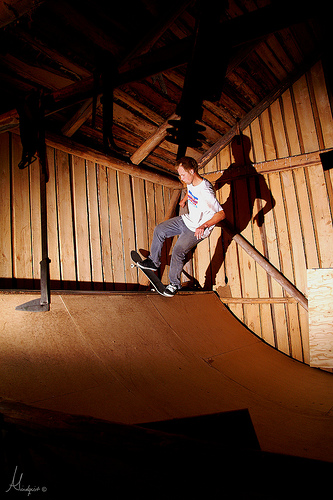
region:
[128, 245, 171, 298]
the skateboard the man is riding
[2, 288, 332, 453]
the ramp the man is skating on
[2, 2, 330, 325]
the building the man is skating in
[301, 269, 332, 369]
a board on the wall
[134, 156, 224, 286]
the man riding a skateboard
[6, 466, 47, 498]
the name in the corner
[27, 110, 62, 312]
the pole by the wall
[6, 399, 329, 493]
the wall by the ramp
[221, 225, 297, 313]
some poles on the wall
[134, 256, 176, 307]
the shoes on the man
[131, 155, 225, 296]
man on a skateboard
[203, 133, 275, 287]
shadow of man on the skateboard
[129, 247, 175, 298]
black skateboard man is on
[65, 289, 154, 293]
top ledge of skateboard ramp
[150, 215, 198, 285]
pants of man on skateboard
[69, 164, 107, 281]
wall behind skateboard ramp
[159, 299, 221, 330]
part of ramp below the skateboard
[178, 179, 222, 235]
shirt man on skateboard is wearing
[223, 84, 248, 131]
ceiling above the skateboarder's shadow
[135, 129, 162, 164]
part of wooden beam on ceiling over skateboarder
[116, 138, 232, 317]
a young man riding a skate board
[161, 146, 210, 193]
a young man with short hair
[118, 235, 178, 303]
a black skate board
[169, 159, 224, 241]
a young man wearing a white shirt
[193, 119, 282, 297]
a persons shadow on a wall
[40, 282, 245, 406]
a wooden skateboard ramp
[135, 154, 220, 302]
a young man wearing black tennis shoes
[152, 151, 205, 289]
a young man wearing grey pants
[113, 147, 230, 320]
a young man on a skateboard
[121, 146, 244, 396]
a young man on a skateboard ramp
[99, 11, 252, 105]
a brown wooden ceiling.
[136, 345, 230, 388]
a smooth skateboard ramp.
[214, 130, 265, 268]
a shadow of a man.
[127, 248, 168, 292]
a black skateboard.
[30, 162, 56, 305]
a black metal instrument.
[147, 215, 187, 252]
a man is wearing grey pants.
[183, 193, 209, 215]
a man is wearing a white red and blue shirt.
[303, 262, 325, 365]
a piece of board.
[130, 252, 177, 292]
a man is wearing black sneakers.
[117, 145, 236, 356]
a man is skateboarding down the ramp.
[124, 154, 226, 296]
The skateboarder currently riding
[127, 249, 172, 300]
The skateboard currently being ridden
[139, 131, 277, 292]
The shadow of the skateboarder on the wall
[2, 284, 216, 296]
The rail on top of the ramp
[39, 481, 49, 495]
The copyright symbol on the photo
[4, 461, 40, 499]
The name of the photographer on the photo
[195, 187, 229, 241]
The left arm of the boarder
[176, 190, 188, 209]
The right arm of the boarder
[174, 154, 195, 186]
The head of the skateboarder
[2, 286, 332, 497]
The ramp the boarder is on